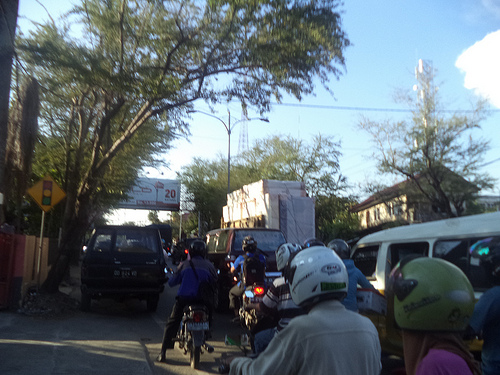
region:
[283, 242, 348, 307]
head of a person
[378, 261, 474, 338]
head of a person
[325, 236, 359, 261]
head of a person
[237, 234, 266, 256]
head of a person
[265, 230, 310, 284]
head of a person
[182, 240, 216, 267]
head of a person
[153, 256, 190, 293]
arm of a person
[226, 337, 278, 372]
arm of a person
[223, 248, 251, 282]
arm of a person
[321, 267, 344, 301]
par of a line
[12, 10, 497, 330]
a street full of busy traffic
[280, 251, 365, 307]
a white motorcycle helmet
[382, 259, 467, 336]
a green motorcycle helmet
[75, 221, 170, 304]
an old battered SUV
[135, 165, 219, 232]
an advertising billboard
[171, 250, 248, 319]
a man carrying a black messenger back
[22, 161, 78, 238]
a street sign indicating a traffic light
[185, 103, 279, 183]
a light post with 2 lamps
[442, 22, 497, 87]
a big fluffy cloud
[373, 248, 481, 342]
green hard helmet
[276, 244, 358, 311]
white hard helmet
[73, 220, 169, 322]
back of van on sidewalk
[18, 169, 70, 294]
yellow traffic sign on metal pole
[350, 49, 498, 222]
tall tree with bare branches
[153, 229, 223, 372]
person on motorcycle in street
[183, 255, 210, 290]
black shoulder strap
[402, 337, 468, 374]
purple shirt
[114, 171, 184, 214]
billboard over street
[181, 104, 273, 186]
double street lamp on pole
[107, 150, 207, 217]
a white and red billboard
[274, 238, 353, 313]
a white and black helmet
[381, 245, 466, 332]
a green and black helmet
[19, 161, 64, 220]
a yellow sign with street light on it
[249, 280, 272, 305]
a lit taillight on motorcycle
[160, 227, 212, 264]
a shiny black helmet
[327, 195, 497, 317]
part of a white van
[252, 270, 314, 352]
a brown and white striped shirt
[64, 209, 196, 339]
a vehicle parked at the curb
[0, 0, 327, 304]
a tall tree by the road